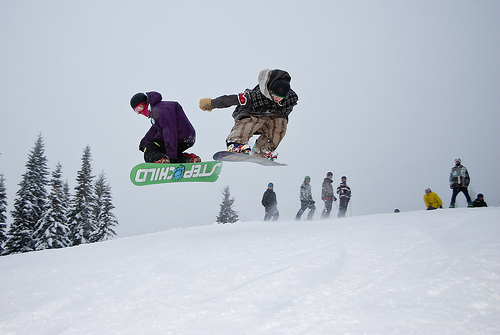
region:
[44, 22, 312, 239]
people snowboarding on the snow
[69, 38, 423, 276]
people snowboarding in the air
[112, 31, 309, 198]
two people snowboarding in the air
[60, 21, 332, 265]
two people jumping in the air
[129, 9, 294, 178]
snowboarders in the air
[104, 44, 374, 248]
two snowboarders in the air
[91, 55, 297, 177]
snowboarders doing a jump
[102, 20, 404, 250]
two snowboarders doing a jump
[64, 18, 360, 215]
a person wearing a purple jacket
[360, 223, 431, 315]
a ground covered in snow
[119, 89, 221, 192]
showboarder in mid air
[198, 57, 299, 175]
snowboarder doing jump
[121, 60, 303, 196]
two snowboarders in the air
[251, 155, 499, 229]
group of people on snowy hill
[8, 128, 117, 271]
several pine trees in the snow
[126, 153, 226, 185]
green stepchild brand snowboard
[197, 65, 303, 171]
snowboarder with plaid pants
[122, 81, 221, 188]
snowboarder with blue jacket and red mask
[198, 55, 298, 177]
showboarder with olive green hat and tan gloves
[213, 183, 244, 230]
one snowy pine tree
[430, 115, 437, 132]
part of the cloud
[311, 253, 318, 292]
part of a hill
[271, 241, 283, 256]
side of a hill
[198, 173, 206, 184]
part of a board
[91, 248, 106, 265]
edge of a tree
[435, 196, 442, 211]
part of an arm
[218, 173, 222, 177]
edge of a board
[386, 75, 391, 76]
part of a cloud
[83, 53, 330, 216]
two young men snowboarding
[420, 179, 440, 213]
a person wearing a yellow coat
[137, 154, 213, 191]
a green and white snowboard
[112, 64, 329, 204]
two young men in the air on a snowboard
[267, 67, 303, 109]
a young man wearing a hat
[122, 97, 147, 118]
a young man wearing goggles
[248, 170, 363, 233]
four young men standing in the snow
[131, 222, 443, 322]
tracks in the snow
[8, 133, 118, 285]
trees covered in snow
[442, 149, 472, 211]
a man standing on a hill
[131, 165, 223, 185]
a green skiing board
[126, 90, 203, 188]
a man in the air skiing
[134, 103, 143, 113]
skiing glasses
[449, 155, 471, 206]
a man standing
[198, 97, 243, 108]
the hand of a skiing man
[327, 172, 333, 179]
the head of an onlooking man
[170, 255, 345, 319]
white snow on the slopes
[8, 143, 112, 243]
trees full of snow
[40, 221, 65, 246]
leaves of a tree covered with snow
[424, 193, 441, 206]
a yellow snow jacket